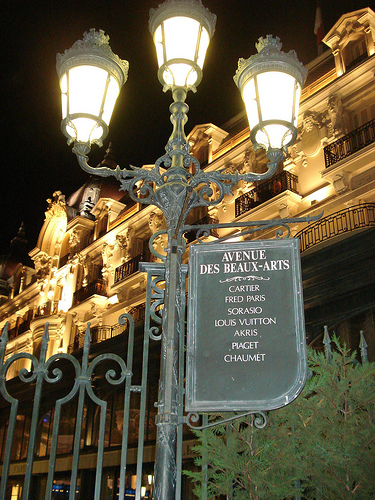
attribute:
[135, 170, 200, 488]
pole — black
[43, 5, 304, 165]
lights — three, yellow, on, glowing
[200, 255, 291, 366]
words — french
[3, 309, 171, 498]
fence — green, metallic, metal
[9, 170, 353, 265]
building — glowing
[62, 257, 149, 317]
balcony — black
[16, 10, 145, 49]
sky — dark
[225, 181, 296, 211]
railing — black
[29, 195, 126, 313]
facade — decorated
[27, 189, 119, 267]
windows — architectural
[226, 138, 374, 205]
railings — black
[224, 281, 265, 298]
word — cartier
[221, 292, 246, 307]
word — fred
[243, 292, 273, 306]
word — paris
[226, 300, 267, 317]
word — sorasio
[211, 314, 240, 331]
word — louis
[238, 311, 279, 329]
word — vuitton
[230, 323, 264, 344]
word — akris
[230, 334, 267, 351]
word — piaget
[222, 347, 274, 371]
word — chaumet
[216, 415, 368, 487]
trees — green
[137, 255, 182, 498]
stand — metallic